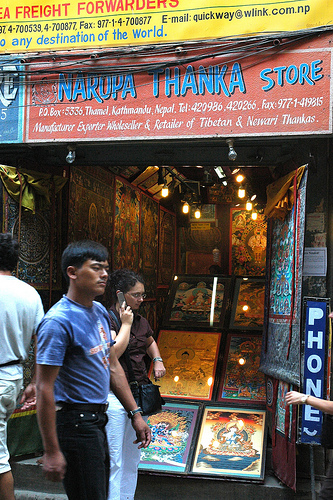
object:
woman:
[109, 268, 167, 500]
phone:
[117, 290, 127, 310]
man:
[33, 242, 153, 500]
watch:
[127, 406, 144, 419]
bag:
[141, 382, 162, 413]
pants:
[54, 401, 112, 499]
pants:
[105, 390, 142, 499]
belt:
[56, 401, 110, 412]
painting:
[148, 326, 219, 398]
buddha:
[172, 346, 195, 375]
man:
[0, 232, 44, 491]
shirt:
[0, 273, 46, 368]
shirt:
[34, 297, 117, 404]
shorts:
[0, 364, 24, 474]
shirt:
[109, 309, 153, 392]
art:
[139, 276, 272, 477]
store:
[0, 141, 331, 484]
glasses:
[124, 293, 146, 298]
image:
[89, 320, 112, 369]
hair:
[107, 268, 146, 292]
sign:
[22, 47, 328, 138]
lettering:
[57, 59, 323, 101]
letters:
[32, 95, 326, 133]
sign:
[303, 299, 325, 443]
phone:
[304, 307, 323, 422]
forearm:
[284, 390, 333, 413]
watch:
[302, 395, 311, 405]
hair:
[0, 232, 20, 273]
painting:
[192, 406, 267, 480]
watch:
[153, 356, 164, 362]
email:
[161, 5, 311, 23]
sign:
[0, 0, 331, 46]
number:
[178, 100, 257, 113]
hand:
[119, 300, 134, 325]